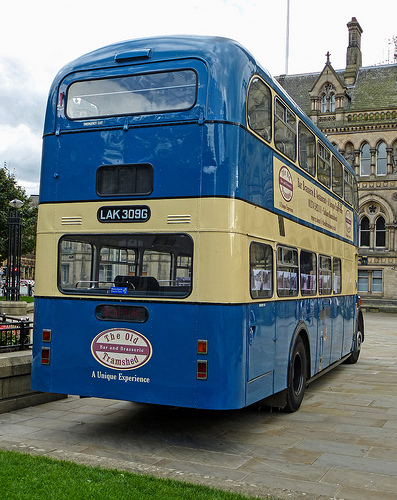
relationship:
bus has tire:
[27, 32, 365, 409] [266, 327, 308, 415]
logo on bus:
[89, 325, 153, 372] [27, 32, 365, 409]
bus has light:
[27, 32, 365, 409] [39, 325, 54, 346]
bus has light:
[27, 32, 365, 409] [194, 336, 210, 357]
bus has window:
[27, 32, 365, 409] [64, 66, 200, 122]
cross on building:
[323, 50, 334, 64] [269, 12, 396, 317]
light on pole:
[6, 195, 27, 212] [10, 209, 18, 303]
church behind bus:
[269, 12, 396, 317] [27, 32, 365, 409]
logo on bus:
[277, 162, 297, 204] [27, 32, 365, 409]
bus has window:
[27, 32, 365, 409] [243, 69, 275, 151]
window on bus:
[273, 86, 299, 167] [27, 32, 365, 409]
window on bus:
[295, 113, 318, 184] [27, 32, 365, 409]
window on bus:
[315, 134, 333, 196] [27, 32, 365, 409]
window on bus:
[330, 147, 344, 202] [27, 32, 365, 409]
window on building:
[355, 134, 374, 179] [269, 12, 396, 317]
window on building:
[373, 136, 389, 178] [269, 12, 396, 317]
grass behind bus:
[0, 447, 253, 499] [27, 32, 365, 409]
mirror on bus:
[358, 252, 370, 269] [27, 32, 365, 409]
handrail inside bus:
[64, 80, 200, 101] [27, 32, 365, 409]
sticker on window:
[107, 284, 130, 296] [55, 230, 196, 301]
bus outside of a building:
[27, 32, 365, 409] [212, 6, 384, 330]